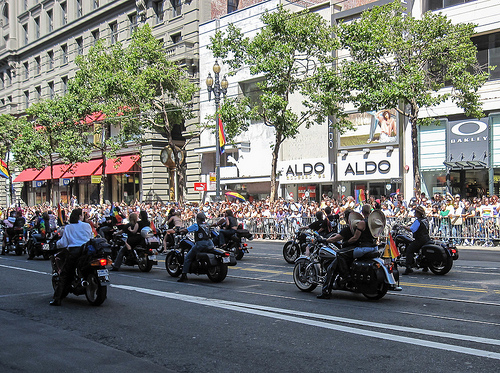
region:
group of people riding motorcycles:
[35, 184, 446, 311]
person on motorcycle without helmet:
[35, 210, 106, 310]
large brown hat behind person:
[368, 212, 398, 235]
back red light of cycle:
[98, 255, 108, 267]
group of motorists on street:
[0, 198, 372, 304]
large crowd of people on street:
[223, 193, 305, 231]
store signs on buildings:
[243, 148, 396, 190]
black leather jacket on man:
[183, 219, 219, 241]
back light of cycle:
[218, 248, 239, 261]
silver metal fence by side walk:
[427, 215, 494, 253]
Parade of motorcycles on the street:
[4, 193, 474, 313]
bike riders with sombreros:
[293, 202, 408, 300]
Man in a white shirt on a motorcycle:
[31, 209, 136, 304]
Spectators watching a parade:
[247, 192, 297, 239]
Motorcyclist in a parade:
[166, 208, 233, 282]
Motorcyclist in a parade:
[35, 199, 120, 313]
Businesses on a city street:
[2, 130, 499, 207]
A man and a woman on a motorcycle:
[113, 210, 168, 272]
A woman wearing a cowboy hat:
[396, 206, 474, 281]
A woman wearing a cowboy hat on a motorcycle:
[396, 203, 473, 282]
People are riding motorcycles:
[2, 190, 460, 309]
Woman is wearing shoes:
[45, 290, 72, 307]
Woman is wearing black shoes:
[47, 294, 63, 307]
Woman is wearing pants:
[54, 241, 89, 302]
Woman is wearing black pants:
[47, 246, 94, 297]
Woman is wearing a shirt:
[50, 218, 99, 249]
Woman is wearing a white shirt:
[52, 222, 102, 246]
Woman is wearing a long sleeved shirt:
[51, 218, 96, 248]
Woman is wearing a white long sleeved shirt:
[57, 220, 99, 248]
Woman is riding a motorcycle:
[37, 206, 112, 306]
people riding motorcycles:
[1, 199, 463, 316]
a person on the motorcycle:
[43, 206, 110, 308]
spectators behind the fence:
[246, 177, 285, 268]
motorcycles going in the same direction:
[3, 198, 465, 326]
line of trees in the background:
[1, 7, 486, 193]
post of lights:
[203, 58, 230, 190]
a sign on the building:
[283, 159, 325, 176]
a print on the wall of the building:
[338, 108, 395, 144]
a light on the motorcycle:
[98, 258, 108, 266]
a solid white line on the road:
[2, 259, 43, 279]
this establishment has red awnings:
[13, 101, 153, 201]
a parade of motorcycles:
[3, 200, 459, 304]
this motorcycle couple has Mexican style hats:
[330, 205, 386, 259]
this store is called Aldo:
[280, 152, 398, 194]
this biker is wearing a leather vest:
[386, 205, 457, 272]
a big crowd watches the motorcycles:
[3, 195, 498, 246]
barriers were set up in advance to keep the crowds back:
[2, 192, 499, 250]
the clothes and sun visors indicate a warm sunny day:
[201, 194, 331, 237]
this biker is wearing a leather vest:
[164, 210, 232, 283]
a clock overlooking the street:
[156, 140, 188, 211]